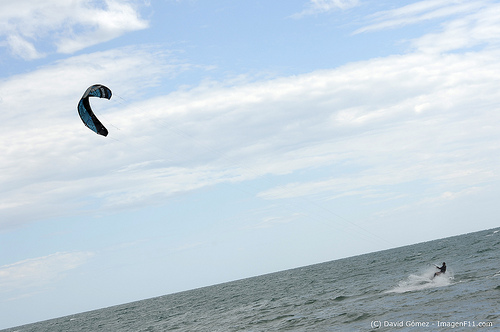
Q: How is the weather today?
A: It is cloudy.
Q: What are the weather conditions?
A: It is cloudy.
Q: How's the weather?
A: It is cloudy.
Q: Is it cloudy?
A: Yes, it is cloudy.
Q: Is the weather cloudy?
A: Yes, it is cloudy.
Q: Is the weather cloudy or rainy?
A: It is cloudy.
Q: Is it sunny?
A: No, it is cloudy.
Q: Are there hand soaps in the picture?
A: No, there are no hand soaps.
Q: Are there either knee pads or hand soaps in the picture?
A: No, there are no hand soaps or knee pads.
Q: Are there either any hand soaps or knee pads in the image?
A: No, there are no hand soaps or knee pads.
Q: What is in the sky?
A: The clouds are in the sky.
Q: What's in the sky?
A: The clouds are in the sky.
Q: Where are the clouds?
A: The clouds are in the sky.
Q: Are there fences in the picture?
A: No, there are no fences.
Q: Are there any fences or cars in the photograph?
A: No, there are no fences or cars.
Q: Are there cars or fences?
A: No, there are no fences or cars.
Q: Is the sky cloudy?
A: Yes, the sky is cloudy.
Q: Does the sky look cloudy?
A: Yes, the sky is cloudy.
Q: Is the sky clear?
A: No, the sky is cloudy.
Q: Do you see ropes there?
A: No, there are no ropes.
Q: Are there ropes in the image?
A: No, there are no ropes.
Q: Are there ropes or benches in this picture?
A: No, there are no ropes or benches.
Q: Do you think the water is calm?
A: Yes, the water is calm.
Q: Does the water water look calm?
A: Yes, the water is calm.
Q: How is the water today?
A: The water is calm.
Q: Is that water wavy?
A: No, the water is calm.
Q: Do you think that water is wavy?
A: No, the water is calm.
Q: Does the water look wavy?
A: No, the water is calm.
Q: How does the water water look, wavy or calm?
A: The water is calm.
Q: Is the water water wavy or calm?
A: The water is calm.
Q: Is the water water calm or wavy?
A: The water is calm.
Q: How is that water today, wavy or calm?
A: The water is calm.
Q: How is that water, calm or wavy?
A: The water is calm.